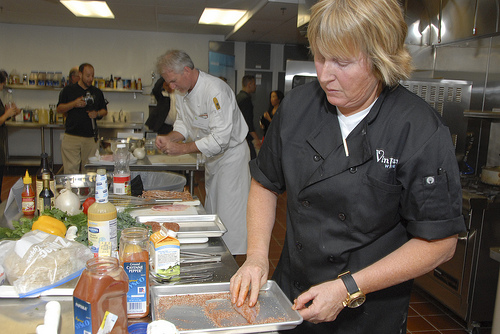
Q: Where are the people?
A: In the kitchen.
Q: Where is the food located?
A: On the table.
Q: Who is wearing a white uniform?
A: A man.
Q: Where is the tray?
A: On the table.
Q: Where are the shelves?
A: In the distance.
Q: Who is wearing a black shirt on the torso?
A: A man.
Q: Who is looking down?
A: The man.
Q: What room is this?
A: Kitchen.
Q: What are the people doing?
A: Cooking.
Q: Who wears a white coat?
A: Chef.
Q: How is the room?
A: Lit.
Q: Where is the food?
A: On the tables.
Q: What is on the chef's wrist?
A: Watch.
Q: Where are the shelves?
A: Wall.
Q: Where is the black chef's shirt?
A: On the woman.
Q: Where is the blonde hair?
A: On the woman's head.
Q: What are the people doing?
A: Cooking.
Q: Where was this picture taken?
A: Restaurant.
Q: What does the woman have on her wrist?
A: Watch.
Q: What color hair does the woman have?
A: Blonde.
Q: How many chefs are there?
A: 2.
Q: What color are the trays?
A: Silver.